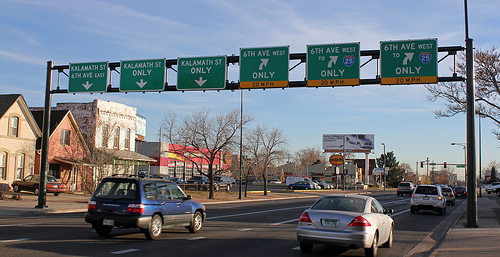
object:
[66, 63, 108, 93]
sign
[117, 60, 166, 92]
sign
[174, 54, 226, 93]
sign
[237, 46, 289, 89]
sign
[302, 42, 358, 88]
sign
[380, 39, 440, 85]
sign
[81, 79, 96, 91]
arrow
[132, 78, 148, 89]
arrow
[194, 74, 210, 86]
arrow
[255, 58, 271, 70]
arrow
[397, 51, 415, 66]
arrow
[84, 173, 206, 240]
car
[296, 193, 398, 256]
car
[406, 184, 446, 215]
car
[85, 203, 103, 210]
tail light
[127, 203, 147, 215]
tail light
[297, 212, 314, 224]
tail light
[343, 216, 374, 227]
tail light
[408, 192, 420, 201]
tail light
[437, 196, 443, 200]
tail light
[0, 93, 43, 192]
house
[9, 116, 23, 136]
window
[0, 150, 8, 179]
window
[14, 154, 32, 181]
window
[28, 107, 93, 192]
house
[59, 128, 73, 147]
window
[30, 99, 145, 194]
building